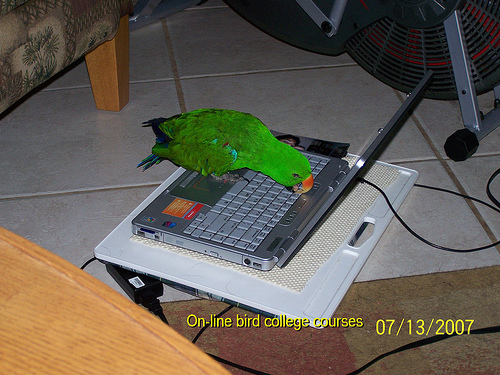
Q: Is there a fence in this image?
A: No, there are no fences.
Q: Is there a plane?
A: No, there are no airplanes.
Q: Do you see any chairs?
A: Yes, there is a chair.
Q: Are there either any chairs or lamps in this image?
A: Yes, there is a chair.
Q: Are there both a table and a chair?
A: Yes, there are both a chair and a table.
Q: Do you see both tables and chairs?
A: Yes, there are both a chair and a table.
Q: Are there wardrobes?
A: No, there are no wardrobes.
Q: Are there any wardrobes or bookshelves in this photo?
A: No, there are no wardrobes or bookshelves.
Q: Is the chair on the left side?
A: Yes, the chair is on the left of the image.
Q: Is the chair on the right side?
A: No, the chair is on the left of the image.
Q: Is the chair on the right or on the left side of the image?
A: The chair is on the left of the image.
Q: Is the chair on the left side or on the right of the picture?
A: The chair is on the left of the image.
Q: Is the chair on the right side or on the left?
A: The chair is on the left of the image.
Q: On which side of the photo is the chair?
A: The chair is on the left of the image.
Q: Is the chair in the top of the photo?
A: Yes, the chair is in the top of the image.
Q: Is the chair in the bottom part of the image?
A: No, the chair is in the top of the image.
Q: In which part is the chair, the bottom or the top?
A: The chair is in the top of the image.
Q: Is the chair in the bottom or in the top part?
A: The chair is in the top of the image.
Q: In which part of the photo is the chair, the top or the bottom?
A: The chair is in the top of the image.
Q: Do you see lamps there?
A: No, there are no lamps.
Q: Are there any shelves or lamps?
A: No, there are no lamps or shelves.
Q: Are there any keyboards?
A: Yes, there is a keyboard.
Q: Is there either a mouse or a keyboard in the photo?
A: Yes, there is a keyboard.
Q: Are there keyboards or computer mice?
A: Yes, there is a keyboard.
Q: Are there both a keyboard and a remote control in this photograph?
A: No, there is a keyboard but no remote controls.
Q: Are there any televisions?
A: No, there are no televisions.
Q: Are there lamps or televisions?
A: No, there are no televisions or lamps.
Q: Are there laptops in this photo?
A: Yes, there is a laptop.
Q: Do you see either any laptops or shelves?
A: Yes, there is a laptop.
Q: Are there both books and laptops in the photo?
A: No, there is a laptop but no books.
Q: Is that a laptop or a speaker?
A: That is a laptop.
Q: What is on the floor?
A: The laptop is on the floor.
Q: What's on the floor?
A: The laptop is on the floor.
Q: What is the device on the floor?
A: The device is a laptop.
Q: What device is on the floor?
A: The device is a laptop.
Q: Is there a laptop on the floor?
A: Yes, there is a laptop on the floor.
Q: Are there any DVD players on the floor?
A: No, there is a laptop on the floor.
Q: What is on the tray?
A: The laptop is on the tray.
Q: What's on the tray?
A: The laptop is on the tray.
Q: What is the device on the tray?
A: The device is a laptop.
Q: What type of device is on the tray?
A: The device is a laptop.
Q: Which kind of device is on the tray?
A: The device is a laptop.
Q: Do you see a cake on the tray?
A: No, there is a laptop on the tray.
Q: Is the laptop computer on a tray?
A: Yes, the laptop computer is on a tray.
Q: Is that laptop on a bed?
A: No, the laptop is on a tray.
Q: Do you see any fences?
A: No, there are no fences.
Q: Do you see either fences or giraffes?
A: No, there are no fences or giraffes.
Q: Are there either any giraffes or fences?
A: No, there are no fences or giraffes.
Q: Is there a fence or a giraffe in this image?
A: No, there are no fences or giraffes.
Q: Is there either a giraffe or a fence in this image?
A: No, there are no fences or giraffes.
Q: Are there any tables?
A: Yes, there is a table.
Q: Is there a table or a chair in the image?
A: Yes, there is a table.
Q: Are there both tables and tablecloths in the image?
A: No, there is a table but no tablecloths.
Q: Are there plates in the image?
A: No, there are no plates.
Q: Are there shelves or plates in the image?
A: No, there are no plates or shelves.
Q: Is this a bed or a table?
A: This is a table.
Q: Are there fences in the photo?
A: No, there are no fences.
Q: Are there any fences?
A: No, there are no fences.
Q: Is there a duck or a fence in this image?
A: No, there are no fences or ducks.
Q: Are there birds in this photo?
A: Yes, there is a bird.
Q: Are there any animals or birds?
A: Yes, there is a bird.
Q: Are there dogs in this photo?
A: No, there are no dogs.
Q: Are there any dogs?
A: No, there are no dogs.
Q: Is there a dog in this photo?
A: No, there are no dogs.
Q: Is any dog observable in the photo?
A: No, there are no dogs.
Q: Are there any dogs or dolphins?
A: No, there are no dogs or dolphins.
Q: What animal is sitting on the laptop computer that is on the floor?
A: The bird is sitting on the laptop computer.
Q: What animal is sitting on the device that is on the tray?
A: The bird is sitting on the laptop computer.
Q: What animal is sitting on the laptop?
A: The bird is sitting on the laptop computer.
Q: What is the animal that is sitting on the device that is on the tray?
A: The animal is a bird.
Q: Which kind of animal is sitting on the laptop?
A: The animal is a bird.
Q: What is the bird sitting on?
A: The bird is sitting on the laptop computer.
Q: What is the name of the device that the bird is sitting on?
A: The device is a laptop.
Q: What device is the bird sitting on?
A: The bird is sitting on the laptop.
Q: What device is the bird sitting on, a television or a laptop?
A: The bird is sitting on a laptop.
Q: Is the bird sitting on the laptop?
A: Yes, the bird is sitting on the laptop.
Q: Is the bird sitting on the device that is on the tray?
A: Yes, the bird is sitting on the laptop.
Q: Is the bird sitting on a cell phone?
A: No, the bird is sitting on the laptop.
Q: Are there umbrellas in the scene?
A: No, there are no umbrellas.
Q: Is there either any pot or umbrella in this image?
A: No, there are no umbrellas or pots.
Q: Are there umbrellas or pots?
A: No, there are no umbrellas or pots.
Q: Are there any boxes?
A: No, there are no boxes.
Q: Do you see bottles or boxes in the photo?
A: No, there are no boxes or bottles.